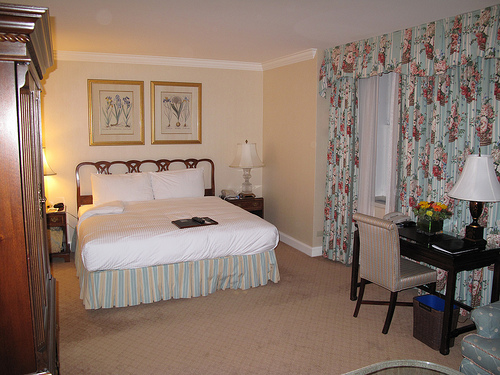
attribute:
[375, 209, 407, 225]
phone — off white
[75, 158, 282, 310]
bed — made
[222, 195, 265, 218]
stand — present, wooden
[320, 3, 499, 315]
curtain — floral print, blue, large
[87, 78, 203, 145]
pictures — framed, hanging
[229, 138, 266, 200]
lamp — white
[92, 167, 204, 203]
pillows — white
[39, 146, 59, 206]
lamp — on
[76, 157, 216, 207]
headboard — wooden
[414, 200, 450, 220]
flowers — hanging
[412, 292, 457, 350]
trash bin — wicker, small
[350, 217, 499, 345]
desk — dark colored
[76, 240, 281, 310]
bed skirt — beige, blue